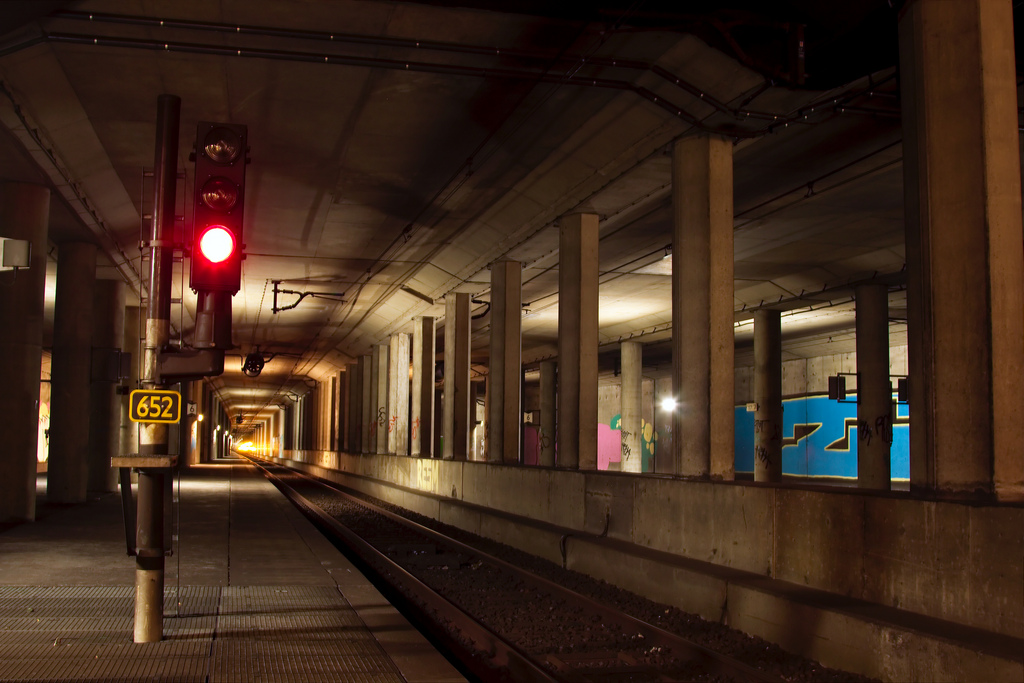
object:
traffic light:
[176, 106, 256, 302]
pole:
[130, 77, 192, 654]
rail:
[274, 449, 780, 668]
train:
[195, 382, 805, 679]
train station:
[9, 6, 1020, 678]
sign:
[123, 382, 186, 424]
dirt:
[249, 452, 867, 679]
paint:
[595, 418, 623, 468]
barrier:
[266, 443, 981, 679]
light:
[198, 225, 237, 264]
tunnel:
[5, 7, 993, 679]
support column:
[436, 290, 471, 459]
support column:
[406, 305, 433, 455]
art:
[733, 385, 913, 483]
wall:
[514, 310, 916, 483]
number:
[135, 394, 150, 419]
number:
[147, 394, 162, 418]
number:
[161, 394, 175, 419]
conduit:
[5, 32, 897, 136]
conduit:
[3, 5, 903, 129]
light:
[228, 439, 275, 453]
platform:
[2, 448, 467, 678]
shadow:
[235, 126, 452, 232]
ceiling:
[5, 3, 909, 434]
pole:
[892, 3, 991, 494]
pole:
[668, 124, 740, 481]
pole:
[551, 210, 598, 474]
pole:
[482, 255, 525, 463]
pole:
[89, 239, 134, 502]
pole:
[109, 271, 192, 643]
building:
[0, 0, 1023, 682]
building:
[714, 308, 903, 483]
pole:
[744, 308, 783, 508]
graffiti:
[714, 384, 938, 479]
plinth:
[38, 222, 129, 503]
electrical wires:
[404, 32, 621, 226]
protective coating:
[143, 142, 601, 508]